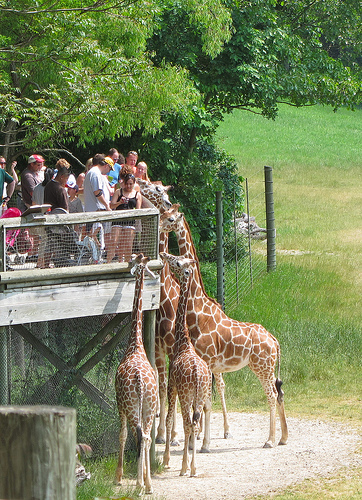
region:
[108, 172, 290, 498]
THE GIRAFFES ARE AT THE RAILING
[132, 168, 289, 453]
TWO GIRAFFES ARE LARGE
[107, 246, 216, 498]
TWO GIRAFFES ARE SMALL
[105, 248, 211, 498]
TWO GIRAFFES ARE YOUNG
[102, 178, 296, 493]
THE GIRAFFES HAVE SPOTS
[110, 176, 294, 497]
THE GIRAFFE'S SPOTS ARE LIGHT BROWN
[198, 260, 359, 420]
THE GREEN GRASS IS TALL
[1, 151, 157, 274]
THE PEOPLE ARE STANDING AT THE RAIL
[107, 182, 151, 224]
THE GIRL IS WEARING A BLACK TANK TOP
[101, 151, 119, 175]
THE MAN IS WEARING A YELLOW HAT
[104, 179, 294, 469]
four giraffes standing togehter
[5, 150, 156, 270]
people on platform beside giraffes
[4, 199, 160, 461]
platform people are standing on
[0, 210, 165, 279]
railing around platform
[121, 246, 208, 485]
two smaller giraffes by platform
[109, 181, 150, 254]
woman wearing black tank top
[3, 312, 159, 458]
wooden posts holding up platform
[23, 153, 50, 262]
man wearing red and white hat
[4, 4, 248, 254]
trees behind platform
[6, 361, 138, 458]
weeds growing under platform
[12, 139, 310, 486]
four giraffes standing beside people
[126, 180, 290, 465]
four brown and white spotted giraffes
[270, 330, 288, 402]
tail of a giraffe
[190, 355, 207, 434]
tail of a giraffe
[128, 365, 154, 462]
tail of a giraffe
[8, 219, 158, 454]
wooden deck and metal fencing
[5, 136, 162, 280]
people standing on a wooden deck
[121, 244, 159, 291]
head of a giraffe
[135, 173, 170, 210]
head of a giraffe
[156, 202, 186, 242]
head of a giraffe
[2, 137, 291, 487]
people looking the giraffes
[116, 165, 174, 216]
head of giraffe near head of woman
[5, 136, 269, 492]
giraffes watching people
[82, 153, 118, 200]
man wears a yellow cup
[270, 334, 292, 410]
long tail of giraffe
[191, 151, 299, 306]
poles of fence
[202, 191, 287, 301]
fence is wired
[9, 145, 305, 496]
giraffes in front a high platform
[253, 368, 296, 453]
back legs of giraffe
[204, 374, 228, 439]
front legs of giraffes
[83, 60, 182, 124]
leaves on the tree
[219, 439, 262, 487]
dirt under the giraffe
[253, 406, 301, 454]
legs of the giraffe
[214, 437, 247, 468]
shadow on the ground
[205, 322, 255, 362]
brown spots on the animal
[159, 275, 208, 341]
neck of the giraffe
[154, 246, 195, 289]
head of the animal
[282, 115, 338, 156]
grass in the distance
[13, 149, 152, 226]
people in the photo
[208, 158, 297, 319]
fence next to the animals